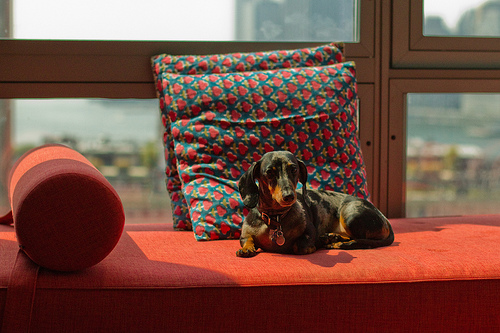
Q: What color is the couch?
A: Red.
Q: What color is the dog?
A: Black, Brown and Grey.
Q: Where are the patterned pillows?
A: Behind the dog.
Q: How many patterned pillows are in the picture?
A: Two.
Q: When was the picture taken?
A: Daytime.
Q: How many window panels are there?
A: Four.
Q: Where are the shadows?
A: On the couch.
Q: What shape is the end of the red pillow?
A: Circle.